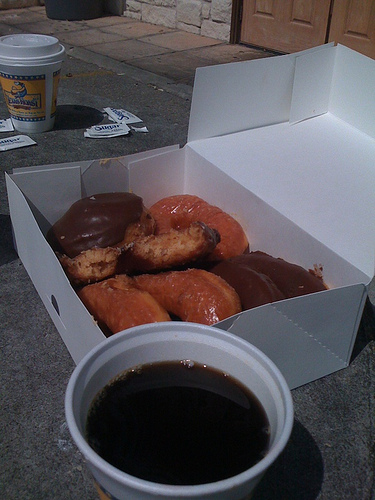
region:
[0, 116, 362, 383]
donuts are in the box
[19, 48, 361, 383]
the box is white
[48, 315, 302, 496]
a cup of coffee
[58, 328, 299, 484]
the coffee is black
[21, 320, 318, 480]
the cup is white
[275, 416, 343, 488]
shadow of the cup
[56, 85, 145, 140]
sugar packs on the floor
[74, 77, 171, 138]
the ground is grey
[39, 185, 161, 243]
the donut has chocolate on it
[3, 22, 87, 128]
the cup has a lid on it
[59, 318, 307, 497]
plastic cup of coffee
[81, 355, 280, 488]
coffee in plastic cup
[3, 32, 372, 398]
white cardboard box of doughnuts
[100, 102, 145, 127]
torn open sugar packet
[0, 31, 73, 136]
disposable drinking cup with lid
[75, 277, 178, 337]
portion of glazed doughnut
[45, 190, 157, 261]
chocolate icing on doughnut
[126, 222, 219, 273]
partially eaten chocolate doughnut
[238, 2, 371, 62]
wooden double doors in background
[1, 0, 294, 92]
red stone walk way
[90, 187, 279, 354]
a delicious sweet items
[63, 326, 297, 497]
a small cup with juice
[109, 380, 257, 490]
juice inside the cup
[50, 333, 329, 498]
a white cup before box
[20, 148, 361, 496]
a box containing food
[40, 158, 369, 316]
a white box with sweets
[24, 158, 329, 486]
a box and cup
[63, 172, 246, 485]
a box with sweet and cup with juice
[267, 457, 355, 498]
shadow of the cup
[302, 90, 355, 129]
light falling on the box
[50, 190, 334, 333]
Donuts in a box.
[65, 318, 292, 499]
A cup of coffee.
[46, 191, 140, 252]
Chocolate icing on the donut.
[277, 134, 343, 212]
Part of the white box.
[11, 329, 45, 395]
Part of the counter.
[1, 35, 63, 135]
A small white cup.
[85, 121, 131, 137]
White packets of sugar.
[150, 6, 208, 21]
Part of the stone wall.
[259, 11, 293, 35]
Part of the brown door.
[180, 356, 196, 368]
Bubbles in the coffee.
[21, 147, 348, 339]
donuts in a box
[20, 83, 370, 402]
a white box with donuts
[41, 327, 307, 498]
a white cup with coffee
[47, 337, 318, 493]
coffee in a white cup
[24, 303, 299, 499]
cup of coffee next to donuts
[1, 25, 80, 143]
a coffee cup with a lid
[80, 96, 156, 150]
white and blue sugar packets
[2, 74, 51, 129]
yellow and blue design on cup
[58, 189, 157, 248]
chocolate frosting on donut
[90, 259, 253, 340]
a few glazed donuts